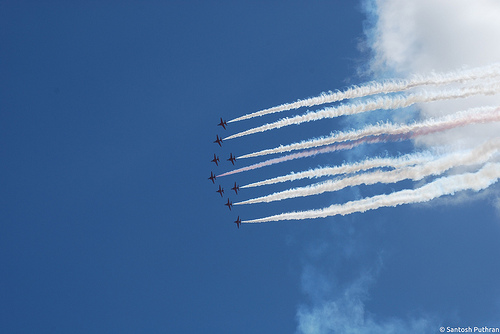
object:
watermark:
[436, 325, 498, 332]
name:
[437, 325, 500, 334]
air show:
[207, 63, 499, 229]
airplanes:
[207, 117, 242, 230]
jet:
[205, 116, 241, 231]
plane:
[207, 117, 243, 229]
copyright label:
[438, 326, 446, 333]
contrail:
[215, 63, 499, 224]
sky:
[0, 14, 496, 328]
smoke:
[214, 62, 499, 225]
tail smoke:
[214, 63, 499, 225]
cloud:
[294, 3, 499, 334]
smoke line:
[221, 61, 498, 224]